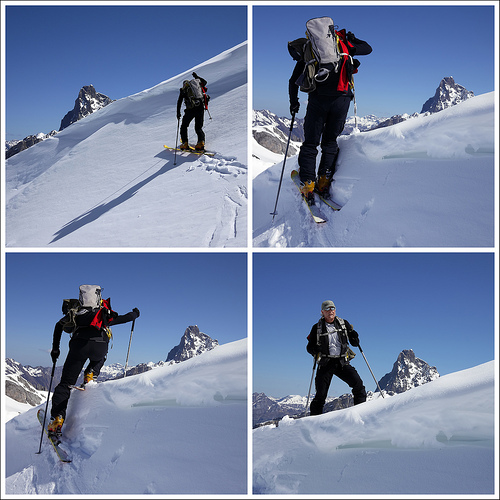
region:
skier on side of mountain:
[165, 71, 243, 164]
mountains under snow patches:
[253, 77, 474, 152]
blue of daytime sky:
[6, 5, 246, 145]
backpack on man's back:
[305, 16, 342, 73]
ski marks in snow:
[202, 153, 247, 179]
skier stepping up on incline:
[38, 284, 138, 464]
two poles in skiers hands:
[304, 330, 384, 414]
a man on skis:
[25, 258, 162, 482]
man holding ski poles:
[292, 283, 396, 439]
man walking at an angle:
[39, 30, 246, 252]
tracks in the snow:
[148, 80, 254, 200]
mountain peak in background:
[368, 318, 462, 416]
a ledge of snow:
[320, 71, 488, 177]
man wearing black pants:
[302, 358, 379, 416]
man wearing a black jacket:
[282, 297, 394, 382]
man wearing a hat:
[310, 290, 345, 332]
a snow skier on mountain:
[160, 68, 212, 157]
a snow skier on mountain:
[270, 16, 375, 224]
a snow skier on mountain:
[32, 280, 140, 465]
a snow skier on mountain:
[305, 295, 385, 415]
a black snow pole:
[171, 115, 181, 162]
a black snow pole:
[35, 356, 56, 453]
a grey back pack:
[185, 75, 203, 100]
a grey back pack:
[305, 12, 341, 65]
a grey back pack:
[77, 281, 102, 314]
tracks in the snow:
[203, 154, 246, 233]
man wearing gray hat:
[298, 298, 375, 407]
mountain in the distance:
[385, 347, 435, 396]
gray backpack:
[72, 284, 102, 310]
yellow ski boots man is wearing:
[43, 369, 96, 434]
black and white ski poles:
[33, 309, 141, 452]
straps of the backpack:
[316, 319, 354, 356]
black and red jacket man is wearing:
[278, 20, 368, 99]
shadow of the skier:
[44, 149, 174, 235]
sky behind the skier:
[255, 255, 490, 406]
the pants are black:
[293, 86, 345, 202]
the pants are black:
[291, 83, 364, 188]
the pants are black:
[293, 82, 351, 186]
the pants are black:
[294, 89, 360, 196]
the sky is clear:
[338, 280, 452, 319]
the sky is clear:
[369, 266, 429, 328]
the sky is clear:
[342, 259, 457, 319]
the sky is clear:
[355, 260, 433, 314]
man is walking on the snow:
[156, 59, 218, 189]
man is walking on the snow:
[146, 56, 213, 197]